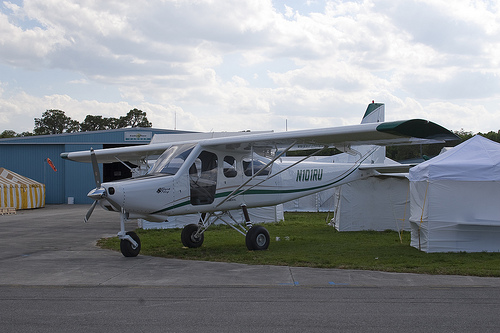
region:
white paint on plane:
[122, 195, 127, 203]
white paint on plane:
[154, 199, 158, 201]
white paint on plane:
[236, 202, 242, 204]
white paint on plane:
[276, 193, 287, 198]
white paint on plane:
[319, 131, 348, 133]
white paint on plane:
[359, 142, 374, 162]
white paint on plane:
[99, 150, 131, 161]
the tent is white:
[403, 145, 498, 271]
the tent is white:
[403, 134, 498, 292]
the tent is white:
[394, 110, 496, 279]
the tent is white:
[409, 122, 496, 264]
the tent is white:
[388, 102, 497, 278]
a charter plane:
[48, 107, 399, 268]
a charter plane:
[43, 102, 403, 256]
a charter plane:
[49, 100, 411, 257]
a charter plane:
[49, 105, 390, 267]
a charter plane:
[52, 108, 439, 284]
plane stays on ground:
[53, 99, 467, 260]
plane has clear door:
[184, 151, 219, 207]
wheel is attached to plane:
[114, 231, 141, 258]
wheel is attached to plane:
[176, 222, 205, 247]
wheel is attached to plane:
[243, 224, 270, 249]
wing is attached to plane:
[45, 113, 460, 167]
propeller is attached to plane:
[70, 144, 130, 228]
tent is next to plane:
[403, 132, 498, 261]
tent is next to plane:
[330, 166, 412, 231]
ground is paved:
[1, 267, 497, 330]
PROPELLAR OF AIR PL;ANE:
[87, 149, 103, 181]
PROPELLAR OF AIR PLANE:
[101, 194, 132, 219]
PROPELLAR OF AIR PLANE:
[74, 201, 101, 233]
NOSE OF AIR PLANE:
[86, 188, 101, 200]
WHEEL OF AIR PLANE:
[114, 230, 146, 260]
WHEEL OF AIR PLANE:
[173, 225, 211, 256]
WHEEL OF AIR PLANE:
[238, 223, 275, 254]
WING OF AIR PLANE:
[233, 118, 453, 160]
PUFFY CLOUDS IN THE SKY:
[228, 14, 278, 49]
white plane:
[45, 95, 452, 263]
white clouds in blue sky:
[40, 22, 90, 70]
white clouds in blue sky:
[175, 42, 237, 84]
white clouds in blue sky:
[74, 38, 119, 65]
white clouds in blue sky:
[267, 41, 304, 68]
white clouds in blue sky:
[387, 26, 448, 74]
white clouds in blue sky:
[148, 12, 209, 46]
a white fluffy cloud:
[178, 39, 273, 86]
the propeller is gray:
[80, 152, 127, 227]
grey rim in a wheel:
[247, 228, 270, 248]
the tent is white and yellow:
[0, 163, 42, 210]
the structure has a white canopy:
[410, 135, 499, 252]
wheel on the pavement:
[110, 223, 142, 262]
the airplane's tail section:
[352, 100, 386, 176]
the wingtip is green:
[374, 110, 459, 147]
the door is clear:
[187, 151, 223, 204]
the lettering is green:
[292, 166, 322, 185]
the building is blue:
[5, 130, 205, 205]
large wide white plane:
[62, 100, 459, 260]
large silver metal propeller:
[81, 149, 122, 221]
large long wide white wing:
[203, 119, 459, 152]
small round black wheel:
[117, 228, 142, 255]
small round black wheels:
[179, 223, 271, 251]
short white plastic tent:
[406, 131, 498, 253]